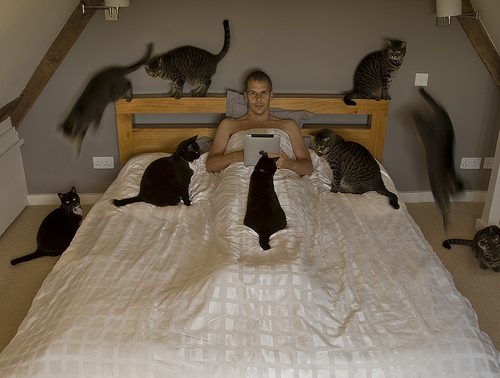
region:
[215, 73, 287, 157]
this is a man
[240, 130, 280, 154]
the man is holding an ipad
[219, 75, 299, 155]
the man is sleeping on bed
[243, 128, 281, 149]
the ipad is white in color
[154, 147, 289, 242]
this are cats on the bed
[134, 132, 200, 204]
the cat is black in color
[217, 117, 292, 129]
the man is bare chested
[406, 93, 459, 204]
the cat is jumping down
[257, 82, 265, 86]
the man is light skinned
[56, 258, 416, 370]
the sheet is white in color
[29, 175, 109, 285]
Black cat on floor beside bed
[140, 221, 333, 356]
Bedspread is white and shiny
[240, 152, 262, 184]
Cat has on red collar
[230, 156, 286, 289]
Cat has black fur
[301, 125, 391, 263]
Tiger striped cat fur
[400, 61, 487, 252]
Cat is jumping off of the bed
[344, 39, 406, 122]
Tiger striped cat sitting on headboard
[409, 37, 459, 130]
Wall is painted gray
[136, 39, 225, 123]
Tiger striped cat standing on headboard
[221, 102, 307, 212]
Man holding Ipad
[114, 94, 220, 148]
Light pine head board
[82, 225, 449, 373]
white window pane checked bed spread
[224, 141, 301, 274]
black cat with red collar.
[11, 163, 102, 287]
a black tuxedo cat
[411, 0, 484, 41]
a wall lamp with white shade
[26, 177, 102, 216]
white baseboard along the floor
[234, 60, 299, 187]
a man on tablet.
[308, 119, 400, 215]
a grey tiger cat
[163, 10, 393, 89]
a beige wall in the bedroom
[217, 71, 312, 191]
man laying in bed with a cat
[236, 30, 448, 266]
man laying in bed with three cats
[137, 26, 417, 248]
man laying in bed with 5 cats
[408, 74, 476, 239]
cat jumping down to floor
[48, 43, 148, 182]
cat jumping off of headboard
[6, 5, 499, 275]
man laying in bed with nine cats around him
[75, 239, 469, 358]
white bedspread on bed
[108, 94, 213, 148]
wooden headboard on bed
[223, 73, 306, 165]
man in bed holding a tablet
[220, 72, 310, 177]
man in bed without a shirt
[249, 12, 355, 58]
this is a wall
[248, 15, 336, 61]
the wall is white in color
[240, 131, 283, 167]
this is an i pad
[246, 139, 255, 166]
the i pad is white in color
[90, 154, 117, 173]
this is a socket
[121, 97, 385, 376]
this is a bed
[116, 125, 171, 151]
the bed is wooden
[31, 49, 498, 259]
these are some cats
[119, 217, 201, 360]
the sheet is white in color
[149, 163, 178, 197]
the fur is black in color